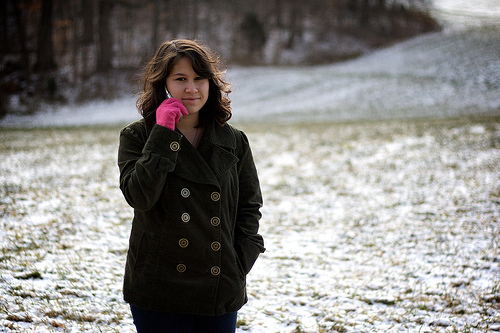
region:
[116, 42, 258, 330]
A young woman on a phone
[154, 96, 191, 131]
Pink glove covered hand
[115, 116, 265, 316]
A brown coat with 10 buttons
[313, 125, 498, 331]
Snow covered grass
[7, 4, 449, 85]
Trees on a rolling hillside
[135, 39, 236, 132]
A woman with shoulder length brown hair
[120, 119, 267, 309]
A winter coat with wide lapels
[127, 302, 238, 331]
Blue jeans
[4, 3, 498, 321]
Snow covered hilly ground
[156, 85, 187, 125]
A cell phone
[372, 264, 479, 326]
fresh snow on the gorund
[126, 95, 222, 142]
pink gloves on a hand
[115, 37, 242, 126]
woman with dark hair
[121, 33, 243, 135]
woman with curly dark hair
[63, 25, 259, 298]
woman in a winter coat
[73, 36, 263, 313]
woman in a dark pea coat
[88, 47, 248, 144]
woman wearing pink gloves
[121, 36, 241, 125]
woman using a cell phone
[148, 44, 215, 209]
woman talking on the phone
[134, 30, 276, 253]
woman talking on the phone outside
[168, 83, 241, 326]
A woman is visible.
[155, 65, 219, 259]
A woman is visible.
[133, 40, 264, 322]
A woman is visible.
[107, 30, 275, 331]
young girl in a peacoat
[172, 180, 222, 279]
eight brassy buttons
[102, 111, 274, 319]
a dark brown peacoat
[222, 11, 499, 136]
snow covered hill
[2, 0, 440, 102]
dense grouping of bare trees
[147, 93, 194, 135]
the young girl's bright pink gloves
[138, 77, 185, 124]
the young girl's using her cell phone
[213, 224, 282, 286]
the girl has her hand in her pocket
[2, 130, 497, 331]
thin layer of snow in a field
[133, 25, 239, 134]
the girl has wavy brown hair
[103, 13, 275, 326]
girl talking on phone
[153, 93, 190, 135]
pink glove on right hand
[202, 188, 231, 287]
buttons on a jacket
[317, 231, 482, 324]
snow on grass ground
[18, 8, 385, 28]
bare trees behind hill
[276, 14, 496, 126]
hills in the distance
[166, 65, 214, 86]
eyes of a woman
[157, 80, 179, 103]
phone in woman's hand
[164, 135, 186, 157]
button on wrist of jacket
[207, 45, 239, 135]
brown curls of a woman's hair